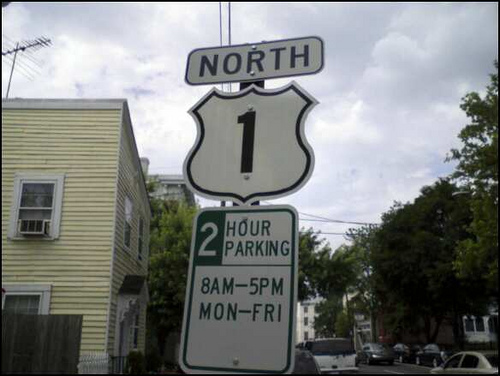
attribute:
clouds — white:
[381, 30, 445, 80]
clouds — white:
[366, 90, 436, 155]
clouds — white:
[331, 74, 370, 208]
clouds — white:
[118, 22, 163, 79]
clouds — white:
[67, 28, 114, 71]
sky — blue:
[10, 11, 483, 193]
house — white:
[0, 96, 146, 373]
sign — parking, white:
[186, 200, 293, 370]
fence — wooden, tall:
[3, 310, 83, 374]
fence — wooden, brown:
[24, 307, 124, 358]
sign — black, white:
[187, 43, 324, 199]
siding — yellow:
[2, 106, 126, 374]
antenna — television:
[0, 34, 51, 99]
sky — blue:
[325, 6, 490, 185]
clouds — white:
[351, 60, 436, 161]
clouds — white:
[318, 37, 460, 188]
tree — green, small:
[365, 179, 488, 359]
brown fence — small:
[0, 310, 82, 374]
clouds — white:
[333, 5, 440, 107]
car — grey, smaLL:
[355, 342, 398, 365]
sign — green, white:
[172, 202, 303, 373]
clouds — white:
[330, 33, 446, 118]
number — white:
[199, 222, 217, 255]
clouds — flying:
[345, 57, 430, 168]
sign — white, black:
[159, 29, 354, 96]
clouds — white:
[44, 58, 204, 169]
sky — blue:
[104, 55, 474, 266]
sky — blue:
[55, 50, 471, 235]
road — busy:
[329, 350, 430, 374]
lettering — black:
[200, 45, 309, 75]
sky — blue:
[15, 5, 484, 226]